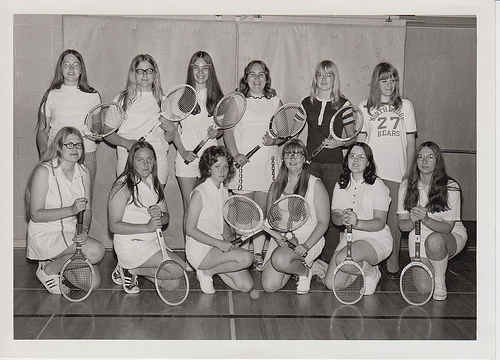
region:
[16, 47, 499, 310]
all girl tennis team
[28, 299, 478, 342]
high shine gym floor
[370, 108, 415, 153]
the Bears team number 27 jersey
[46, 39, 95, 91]
girl wears wire rimmed glasses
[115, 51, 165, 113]
black rimmed glassed on blond girl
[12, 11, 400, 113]
gym mats hang on the wall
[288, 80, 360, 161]
lone dark shirt with stripes sleeves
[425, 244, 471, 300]
white knee high socks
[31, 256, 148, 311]
striped tennis shoes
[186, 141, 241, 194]
one girl with short curly hair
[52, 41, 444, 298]
1970's girls tennis team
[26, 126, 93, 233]
teen girl wearing glasses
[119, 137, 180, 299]
girl holding tennis racket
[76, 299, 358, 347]
shiny wooden gym floor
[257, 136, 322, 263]
girl with pigtails and glasses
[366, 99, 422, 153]
North Ridge Bears jersey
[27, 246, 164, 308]
girls wearing tennis shoes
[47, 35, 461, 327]
group yearbook photo from 1970's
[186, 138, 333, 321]
team members crossing rackets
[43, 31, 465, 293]
tennis team poses for photo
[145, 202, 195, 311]
white tennis racket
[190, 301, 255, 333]
black stripe on the court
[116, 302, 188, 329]
gym court floor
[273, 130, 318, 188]
a woman wearing glasses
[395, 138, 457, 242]
a woman with long dark hair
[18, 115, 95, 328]
a woman kneeling on the ground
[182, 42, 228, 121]
a woman standing by the wall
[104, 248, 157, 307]
woman's tennis shoes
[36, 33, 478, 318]
picture of a girls tennis team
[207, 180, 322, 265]
two tennis rackets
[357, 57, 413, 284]
a female tennis player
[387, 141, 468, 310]
a female tennis player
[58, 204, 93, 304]
a black and white tennis racket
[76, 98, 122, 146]
a tennis racket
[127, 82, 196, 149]
a black and white tennis racket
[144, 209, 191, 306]
a black and white tennis racket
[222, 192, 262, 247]
a black and white tennis racket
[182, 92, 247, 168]
a black and white tennis racket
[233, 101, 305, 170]
a black and white tennis racket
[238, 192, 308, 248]
a black and white tennis racket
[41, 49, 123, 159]
a female tennis player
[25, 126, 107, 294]
a female tennis player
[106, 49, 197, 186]
a female tennis player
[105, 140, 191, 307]
a female tennis player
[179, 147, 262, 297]
a female tennis player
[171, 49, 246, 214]
a female tennis player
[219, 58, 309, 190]
a female tennis player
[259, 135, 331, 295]
a female tennis player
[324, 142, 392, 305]
a female tennis player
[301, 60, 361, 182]
a female tennis player